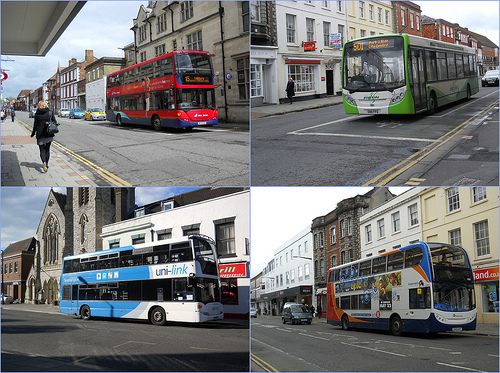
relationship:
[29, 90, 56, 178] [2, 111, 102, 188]
woman walks on sidewalk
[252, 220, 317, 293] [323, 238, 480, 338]
building behind bus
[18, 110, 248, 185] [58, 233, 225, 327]
road near bus